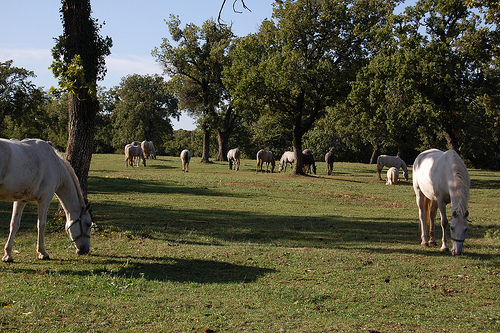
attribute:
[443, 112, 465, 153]
ground — grazing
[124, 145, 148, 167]
horse — white, grazing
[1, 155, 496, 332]
grass — green 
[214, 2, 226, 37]
branch — leafless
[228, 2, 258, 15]
branch — leafless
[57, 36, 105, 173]
tree trunk — tall 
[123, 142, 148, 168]
horse — white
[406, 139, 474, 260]
horse — white 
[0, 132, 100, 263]
horse — black , white, grazing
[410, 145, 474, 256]
horse — white 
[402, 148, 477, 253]
white horse — grazing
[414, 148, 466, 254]
horse — white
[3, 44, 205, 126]
clouds — puffy 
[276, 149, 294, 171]
horse — white, grazing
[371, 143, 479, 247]
horse — white 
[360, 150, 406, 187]
horse — white 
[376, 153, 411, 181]
horse — white, grazing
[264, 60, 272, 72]
leaf — green 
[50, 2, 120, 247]
trunk — brown 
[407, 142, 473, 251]
horse — white